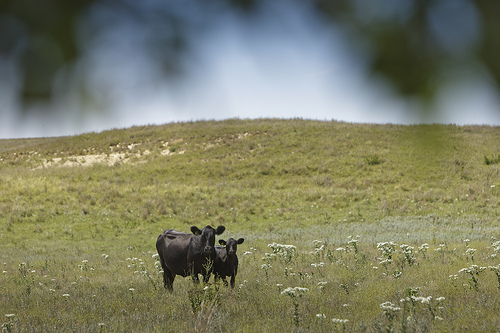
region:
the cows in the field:
[155, 220, 240, 288]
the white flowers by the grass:
[274, 235, 296, 266]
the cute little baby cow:
[216, 231, 246, 286]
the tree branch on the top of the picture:
[2, 5, 497, 112]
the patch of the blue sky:
[204, 35, 341, 118]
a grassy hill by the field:
[2, 124, 497, 186]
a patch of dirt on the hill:
[51, 151, 142, 167]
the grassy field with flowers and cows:
[2, 182, 492, 327]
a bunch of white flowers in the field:
[374, 232, 482, 332]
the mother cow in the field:
[151, 215, 225, 290]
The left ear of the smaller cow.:
[216, 235, 226, 250]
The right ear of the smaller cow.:
[235, 235, 245, 241]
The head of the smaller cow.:
[224, 240, 236, 255]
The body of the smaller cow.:
[212, 248, 241, 273]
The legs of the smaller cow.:
[214, 270, 239, 295]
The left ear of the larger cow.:
[184, 222, 201, 234]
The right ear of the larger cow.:
[214, 226, 227, 237]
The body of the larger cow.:
[154, 231, 203, 273]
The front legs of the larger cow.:
[182, 265, 219, 290]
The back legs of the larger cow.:
[158, 262, 176, 291]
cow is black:
[150, 220, 221, 290]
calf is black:
[211, 235, 246, 287]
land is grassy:
[255, 147, 487, 317]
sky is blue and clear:
[1, 28, 497, 134]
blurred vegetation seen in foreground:
[0, 0, 496, 136]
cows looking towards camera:
[150, 216, 241, 286]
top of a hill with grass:
[1, 110, 493, 190]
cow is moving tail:
[150, 220, 222, 282]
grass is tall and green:
[275, 225, 480, 325]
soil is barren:
[25, 135, 250, 175]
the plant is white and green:
[286, 289, 300, 315]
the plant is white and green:
[283, 248, 304, 315]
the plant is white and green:
[292, 286, 307, 319]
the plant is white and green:
[299, 286, 309, 331]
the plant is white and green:
[272, 276, 298, 325]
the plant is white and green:
[279, 283, 301, 313]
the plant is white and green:
[294, 277, 301, 299]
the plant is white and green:
[291, 279, 298, 307]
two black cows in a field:
[126, 197, 291, 302]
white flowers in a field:
[296, 225, 492, 311]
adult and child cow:
[134, 188, 324, 331]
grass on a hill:
[136, 118, 411, 202]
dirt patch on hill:
[29, 126, 216, 198]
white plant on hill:
[268, 238, 302, 273]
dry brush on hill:
[252, 152, 379, 219]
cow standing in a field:
[113, 199, 219, 288]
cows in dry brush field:
[137, 205, 309, 319]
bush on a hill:
[362, 137, 398, 179]